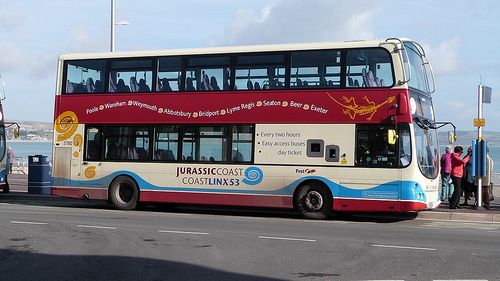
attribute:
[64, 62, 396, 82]
deck — upper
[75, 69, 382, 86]
passenger seats — empty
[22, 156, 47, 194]
bin — blue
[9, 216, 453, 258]
lines — white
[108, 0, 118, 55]
pole — light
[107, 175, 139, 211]
wheel — rear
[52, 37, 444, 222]
bus — Red, white, and blue, double-decker, double decker, large, colorful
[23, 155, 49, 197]
trashcan — blue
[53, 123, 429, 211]
deck — lower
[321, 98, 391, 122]
skeleton — dinosaur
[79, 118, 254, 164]
windows — Passenger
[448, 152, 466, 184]
coat — red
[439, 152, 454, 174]
jacket — fuchsia colored 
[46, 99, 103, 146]
spiral — bright yellow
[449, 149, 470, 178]
coat — red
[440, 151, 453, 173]
jacket — purple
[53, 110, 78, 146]
paint — yellow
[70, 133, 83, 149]
paint — yellow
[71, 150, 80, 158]
paint — yellow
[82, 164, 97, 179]
paint — yellow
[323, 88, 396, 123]
paint — yellow